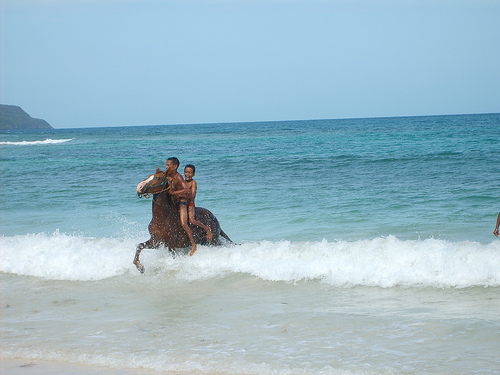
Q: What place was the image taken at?
A: It was taken at the ocean.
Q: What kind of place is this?
A: It is an ocean.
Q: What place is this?
A: It is an ocean.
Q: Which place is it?
A: It is an ocean.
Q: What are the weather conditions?
A: It is clear.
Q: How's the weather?
A: It is clear.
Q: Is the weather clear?
A: Yes, it is clear.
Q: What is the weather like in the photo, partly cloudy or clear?
A: It is clear.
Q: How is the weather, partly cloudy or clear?
A: It is clear.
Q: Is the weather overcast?
A: No, it is clear.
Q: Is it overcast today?
A: No, it is clear.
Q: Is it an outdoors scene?
A: Yes, it is outdoors.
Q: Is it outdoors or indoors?
A: It is outdoors.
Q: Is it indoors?
A: No, it is outdoors.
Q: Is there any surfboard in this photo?
A: No, there are no surfboards.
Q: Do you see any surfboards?
A: No, there are no surfboards.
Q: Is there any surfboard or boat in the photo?
A: No, there are no surfboards or boats.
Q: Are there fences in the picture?
A: No, there are no fences.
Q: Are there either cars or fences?
A: No, there are no fences or cars.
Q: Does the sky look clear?
A: Yes, the sky is clear.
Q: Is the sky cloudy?
A: No, the sky is clear.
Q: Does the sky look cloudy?
A: No, the sky is clear.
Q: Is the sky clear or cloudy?
A: The sky is clear.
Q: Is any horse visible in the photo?
A: Yes, there is a horse.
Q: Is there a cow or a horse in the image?
A: Yes, there is a horse.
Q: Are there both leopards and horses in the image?
A: No, there is a horse but no leopards.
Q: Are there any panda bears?
A: No, there are no panda bears.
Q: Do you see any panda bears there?
A: No, there are no panda bears.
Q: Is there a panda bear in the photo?
A: No, there are no pandas.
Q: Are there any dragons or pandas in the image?
A: No, there are no pandas or dragons.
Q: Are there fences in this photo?
A: No, there are no fences.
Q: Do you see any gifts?
A: No, there are no gifts.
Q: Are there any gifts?
A: No, there are no gifts.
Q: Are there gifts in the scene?
A: No, there are no gifts.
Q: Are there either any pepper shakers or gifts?
A: No, there are no gifts or pepper shakers.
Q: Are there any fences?
A: No, there are no fences.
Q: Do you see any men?
A: No, there are no men.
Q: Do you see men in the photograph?
A: No, there are no men.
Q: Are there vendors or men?
A: No, there are no men or vendors.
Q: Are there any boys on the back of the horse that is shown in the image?
A: Yes, there is a boy on the back of the horse.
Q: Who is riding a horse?
A: The boy is riding a horse.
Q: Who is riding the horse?
A: The boy is riding a horse.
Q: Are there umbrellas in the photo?
A: No, there are no umbrellas.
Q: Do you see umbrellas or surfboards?
A: No, there are no umbrellas or surfboards.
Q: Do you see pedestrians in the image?
A: No, there are no pedestrians.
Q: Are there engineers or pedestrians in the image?
A: No, there are no pedestrians or engineers.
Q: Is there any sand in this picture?
A: Yes, there is sand.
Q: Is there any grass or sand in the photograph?
A: Yes, there is sand.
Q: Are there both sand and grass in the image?
A: No, there is sand but no grass.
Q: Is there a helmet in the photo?
A: No, there are no helmets.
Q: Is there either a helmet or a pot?
A: No, there are no helmets or pots.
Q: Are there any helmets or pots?
A: No, there are no helmets or pots.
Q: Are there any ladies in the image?
A: No, there are no ladies.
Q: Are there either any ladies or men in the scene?
A: No, there are no ladies or men.